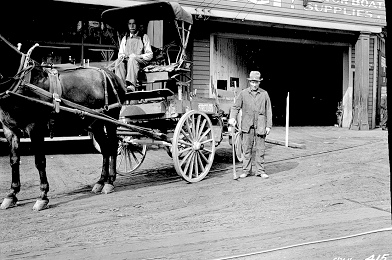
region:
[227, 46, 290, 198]
black and white picture of old man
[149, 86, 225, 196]
black and white photo of cart wheel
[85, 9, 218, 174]
old fashioned picture of man in carriage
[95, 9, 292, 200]
old fashioned black and white picture of two men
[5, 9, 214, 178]
man in horse drawn carriage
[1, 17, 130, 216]
black and white picture of horse in harness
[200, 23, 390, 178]
black and white picture of man standing in front of store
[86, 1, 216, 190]
unsmiling man in old fashioned carriage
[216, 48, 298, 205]
old photograph of man with top hat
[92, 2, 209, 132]
old photograph of man with overalls sitting in horse drawn carriage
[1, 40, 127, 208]
part of a horse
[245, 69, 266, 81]
a man's hat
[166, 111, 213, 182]
the wheel of a wagon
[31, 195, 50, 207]
the hoof of a horse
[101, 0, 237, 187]
a wagon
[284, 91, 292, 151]
a tall white pole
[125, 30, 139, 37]
a man's shirt collar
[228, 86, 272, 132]
a man's old gray jacket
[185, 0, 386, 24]
part of a store sign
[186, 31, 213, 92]
part of a building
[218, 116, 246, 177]
cane in man's hand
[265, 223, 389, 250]
white line on the street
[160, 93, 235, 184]
large wheel on carraige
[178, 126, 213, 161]
spokes in carraige's wheel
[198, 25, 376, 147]
large entrance on building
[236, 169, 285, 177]
man wearing white shoes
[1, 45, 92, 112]
reins around horse's neck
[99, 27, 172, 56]
rider wearing jeans overalls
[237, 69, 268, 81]
wide brimmed tan hat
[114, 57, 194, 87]
seat across the carraige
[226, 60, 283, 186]
man on a dirt road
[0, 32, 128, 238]
horse hitched to a wagon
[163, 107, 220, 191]
wooden wagon wheel on wagon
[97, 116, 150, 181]
wooden wheel on a wagon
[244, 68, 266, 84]
old style hat on head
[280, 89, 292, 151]
wooden post sticking out of the ground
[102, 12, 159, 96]
man on a wagon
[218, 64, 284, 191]
man standing near wagon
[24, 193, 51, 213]
hoof of a horse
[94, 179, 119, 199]
hoof of a horse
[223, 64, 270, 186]
a man standing in dirt street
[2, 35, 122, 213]
a standing horse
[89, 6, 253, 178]
a wooden covered carriage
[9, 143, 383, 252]
an unpaved dirt road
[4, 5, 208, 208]
a horse drawn carriage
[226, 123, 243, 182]
a walking cane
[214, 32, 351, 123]
a large business entryway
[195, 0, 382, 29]
a painted business sign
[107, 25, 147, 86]
a pair of overalls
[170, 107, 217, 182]
a large spoked wagon wheel